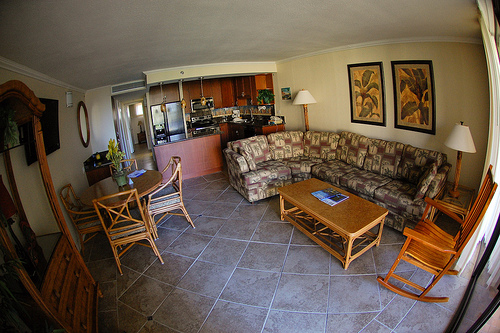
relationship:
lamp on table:
[438, 103, 489, 194] [416, 174, 480, 228]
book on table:
[315, 180, 354, 208] [252, 161, 406, 253]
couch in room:
[213, 115, 474, 212] [4, 31, 470, 325]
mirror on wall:
[68, 88, 109, 141] [0, 89, 122, 268]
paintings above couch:
[330, 45, 461, 154] [213, 115, 474, 212]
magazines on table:
[315, 180, 354, 208] [252, 161, 406, 253]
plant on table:
[99, 142, 152, 204] [64, 147, 182, 254]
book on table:
[309, 187, 351, 205] [252, 161, 406, 253]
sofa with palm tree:
[213, 115, 474, 212] [338, 52, 396, 134]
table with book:
[252, 161, 406, 253] [309, 187, 351, 205]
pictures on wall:
[330, 45, 461, 154] [281, 21, 481, 160]